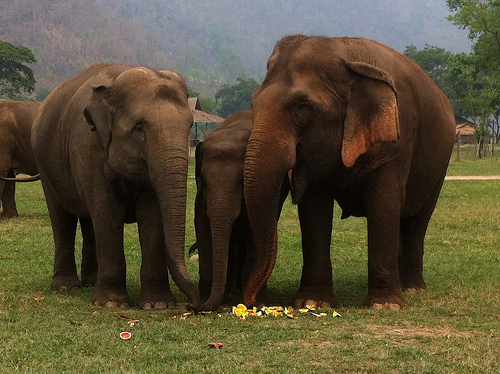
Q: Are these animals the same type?
A: Yes, all the animals are elephants.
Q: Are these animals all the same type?
A: Yes, all the animals are elephants.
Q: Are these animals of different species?
A: No, all the animals are elephants.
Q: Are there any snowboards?
A: No, there are no snowboards.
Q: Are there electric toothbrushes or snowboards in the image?
A: No, there are no snowboards or electric toothbrushes.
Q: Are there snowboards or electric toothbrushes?
A: No, there are no snowboards or electric toothbrushes.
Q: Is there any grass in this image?
A: Yes, there is grass.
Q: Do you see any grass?
A: Yes, there is grass.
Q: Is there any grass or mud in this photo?
A: Yes, there is grass.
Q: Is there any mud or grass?
A: Yes, there is grass.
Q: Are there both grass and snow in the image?
A: No, there is grass but no snow.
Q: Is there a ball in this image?
A: No, there are no balls.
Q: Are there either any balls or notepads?
A: No, there are no balls or notepads.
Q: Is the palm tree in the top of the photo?
A: Yes, the palm tree is in the top of the image.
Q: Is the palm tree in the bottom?
A: No, the palm tree is in the top of the image.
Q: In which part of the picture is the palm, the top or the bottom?
A: The palm is in the top of the image.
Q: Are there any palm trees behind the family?
A: Yes, there is a palm tree behind the family.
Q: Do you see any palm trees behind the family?
A: Yes, there is a palm tree behind the family.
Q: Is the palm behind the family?
A: Yes, the palm is behind the family.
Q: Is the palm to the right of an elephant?
A: Yes, the palm is to the right of an elephant.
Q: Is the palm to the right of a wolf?
A: No, the palm is to the right of an elephant.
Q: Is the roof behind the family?
A: Yes, the roof is behind the family.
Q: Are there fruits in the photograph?
A: Yes, there is a fruit.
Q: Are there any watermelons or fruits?
A: Yes, there is a fruit.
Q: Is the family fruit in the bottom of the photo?
A: Yes, the fruit is in the bottom of the image.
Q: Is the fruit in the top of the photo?
A: No, the fruit is in the bottom of the image.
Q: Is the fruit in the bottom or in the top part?
A: The fruit is in the bottom of the image.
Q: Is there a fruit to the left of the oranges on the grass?
A: Yes, there is a fruit to the left of the oranges.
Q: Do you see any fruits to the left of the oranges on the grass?
A: Yes, there is a fruit to the left of the oranges.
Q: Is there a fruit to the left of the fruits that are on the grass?
A: Yes, there is a fruit to the left of the oranges.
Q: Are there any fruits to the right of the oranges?
A: No, the fruit is to the left of the oranges.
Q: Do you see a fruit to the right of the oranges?
A: No, the fruit is to the left of the oranges.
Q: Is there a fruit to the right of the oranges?
A: No, the fruit is to the left of the oranges.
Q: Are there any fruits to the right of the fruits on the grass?
A: No, the fruit is to the left of the oranges.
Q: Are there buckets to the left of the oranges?
A: No, there is a fruit to the left of the oranges.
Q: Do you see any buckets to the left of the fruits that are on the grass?
A: No, there is a fruit to the left of the oranges.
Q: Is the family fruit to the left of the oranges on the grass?
A: Yes, the fruit is to the left of the oranges.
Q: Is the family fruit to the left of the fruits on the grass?
A: Yes, the fruit is to the left of the oranges.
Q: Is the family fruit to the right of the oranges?
A: No, the fruit is to the left of the oranges.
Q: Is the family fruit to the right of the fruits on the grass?
A: No, the fruit is to the left of the oranges.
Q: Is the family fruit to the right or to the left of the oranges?
A: The fruit is to the left of the oranges.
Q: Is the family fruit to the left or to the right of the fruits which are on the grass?
A: The fruit is to the left of the oranges.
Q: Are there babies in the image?
A: Yes, there is a baby.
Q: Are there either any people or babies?
A: Yes, there is a baby.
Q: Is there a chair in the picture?
A: No, there are no chairs.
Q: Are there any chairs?
A: No, there are no chairs.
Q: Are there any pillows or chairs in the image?
A: No, there are no chairs or pillows.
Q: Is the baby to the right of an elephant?
A: Yes, the baby is to the right of an elephant.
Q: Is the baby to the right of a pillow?
A: No, the baby is to the right of an elephant.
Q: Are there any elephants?
A: Yes, there is an elephant.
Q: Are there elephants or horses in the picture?
A: Yes, there is an elephant.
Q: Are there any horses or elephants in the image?
A: Yes, there is an elephant.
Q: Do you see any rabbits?
A: No, there are no rabbits.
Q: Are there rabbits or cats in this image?
A: No, there are no rabbits or cats.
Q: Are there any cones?
A: No, there are no cones.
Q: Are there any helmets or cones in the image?
A: No, there are no cones or helmets.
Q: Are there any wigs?
A: No, there are no wigs.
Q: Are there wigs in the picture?
A: No, there are no wigs.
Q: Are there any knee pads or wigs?
A: No, there are no wigs or knee pads.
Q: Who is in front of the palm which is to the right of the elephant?
A: The family is in front of the palm.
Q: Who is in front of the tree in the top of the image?
A: The family is in front of the palm.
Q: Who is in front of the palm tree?
A: The family is in front of the palm.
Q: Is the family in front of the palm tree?
A: Yes, the family is in front of the palm tree.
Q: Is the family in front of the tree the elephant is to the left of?
A: Yes, the family is in front of the palm tree.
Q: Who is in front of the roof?
A: The family is in front of the roof.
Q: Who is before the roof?
A: The family is in front of the roof.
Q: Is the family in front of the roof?
A: Yes, the family is in front of the roof.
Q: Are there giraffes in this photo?
A: No, there are no giraffes.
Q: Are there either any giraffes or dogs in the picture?
A: No, there are no giraffes or dogs.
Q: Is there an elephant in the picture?
A: Yes, there is an elephant.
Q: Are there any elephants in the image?
A: Yes, there is an elephant.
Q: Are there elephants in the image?
A: Yes, there is an elephant.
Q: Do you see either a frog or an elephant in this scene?
A: Yes, there is an elephant.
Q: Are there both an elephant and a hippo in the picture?
A: No, there is an elephant but no hippoes.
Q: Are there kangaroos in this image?
A: No, there are no kangaroos.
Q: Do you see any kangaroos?
A: No, there are no kangaroos.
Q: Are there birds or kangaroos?
A: No, there are no kangaroos or birds.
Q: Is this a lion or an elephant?
A: This is an elephant.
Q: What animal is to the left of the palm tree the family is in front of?
A: The animal is an elephant.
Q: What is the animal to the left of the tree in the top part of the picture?
A: The animal is an elephant.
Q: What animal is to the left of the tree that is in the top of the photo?
A: The animal is an elephant.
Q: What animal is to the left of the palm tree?
A: The animal is an elephant.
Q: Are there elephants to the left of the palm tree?
A: Yes, there is an elephant to the left of the palm tree.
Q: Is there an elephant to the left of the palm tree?
A: Yes, there is an elephant to the left of the palm tree.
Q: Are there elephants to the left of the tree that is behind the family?
A: Yes, there is an elephant to the left of the palm tree.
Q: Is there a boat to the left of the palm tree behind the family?
A: No, there is an elephant to the left of the palm tree.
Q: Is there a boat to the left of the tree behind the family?
A: No, there is an elephant to the left of the palm tree.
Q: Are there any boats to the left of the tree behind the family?
A: No, there is an elephant to the left of the palm tree.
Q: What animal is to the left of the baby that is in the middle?
A: The animal is an elephant.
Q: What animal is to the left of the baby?
A: The animal is an elephant.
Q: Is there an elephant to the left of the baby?
A: Yes, there is an elephant to the left of the baby.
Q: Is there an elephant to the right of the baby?
A: No, the elephant is to the left of the baby.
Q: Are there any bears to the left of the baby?
A: No, there is an elephant to the left of the baby.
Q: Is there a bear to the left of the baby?
A: No, there is an elephant to the left of the baby.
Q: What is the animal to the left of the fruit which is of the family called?
A: The animal is an elephant.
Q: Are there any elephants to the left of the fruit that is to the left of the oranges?
A: Yes, there is an elephant to the left of the fruit.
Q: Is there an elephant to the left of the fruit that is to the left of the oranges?
A: Yes, there is an elephant to the left of the fruit.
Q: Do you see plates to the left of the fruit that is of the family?
A: No, there is an elephant to the left of the fruit.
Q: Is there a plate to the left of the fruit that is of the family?
A: No, there is an elephant to the left of the fruit.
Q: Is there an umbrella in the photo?
A: No, there are no umbrellas.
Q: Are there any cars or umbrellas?
A: No, there are no umbrellas or cars.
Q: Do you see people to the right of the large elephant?
A: Yes, there are people to the right of the elephant.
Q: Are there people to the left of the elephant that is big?
A: No, the people are to the right of the elephant.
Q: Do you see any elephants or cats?
A: Yes, there is an elephant.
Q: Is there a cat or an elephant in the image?
A: Yes, there is an elephant.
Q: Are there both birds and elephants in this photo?
A: No, there is an elephant but no birds.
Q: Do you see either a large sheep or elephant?
A: Yes, there is a large elephant.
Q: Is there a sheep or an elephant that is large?
A: Yes, the elephant is large.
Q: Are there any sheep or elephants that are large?
A: Yes, the elephant is large.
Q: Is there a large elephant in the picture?
A: Yes, there is a large elephant.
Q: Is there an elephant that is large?
A: Yes, there is an elephant that is large.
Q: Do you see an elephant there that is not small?
A: Yes, there is a large elephant.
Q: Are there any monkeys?
A: No, there are no monkeys.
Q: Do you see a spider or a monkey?
A: No, there are no monkeys or spiders.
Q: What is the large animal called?
A: The animal is an elephant.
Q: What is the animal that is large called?
A: The animal is an elephant.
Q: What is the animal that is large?
A: The animal is an elephant.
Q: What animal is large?
A: The animal is an elephant.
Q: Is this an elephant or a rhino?
A: This is an elephant.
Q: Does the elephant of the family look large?
A: Yes, the elephant is large.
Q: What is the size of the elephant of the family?
A: The elephant is large.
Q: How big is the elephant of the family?
A: The elephant is large.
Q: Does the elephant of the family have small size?
A: No, the elephant is large.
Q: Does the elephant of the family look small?
A: No, the elephant is large.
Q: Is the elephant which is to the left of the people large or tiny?
A: The elephant is large.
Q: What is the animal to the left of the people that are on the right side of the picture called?
A: The animal is an elephant.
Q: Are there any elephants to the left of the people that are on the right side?
A: Yes, there is an elephant to the left of the people.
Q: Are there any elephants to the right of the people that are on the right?
A: No, the elephant is to the left of the people.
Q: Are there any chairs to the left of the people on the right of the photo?
A: No, there is an elephant to the left of the people.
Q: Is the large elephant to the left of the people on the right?
A: Yes, the elephant is to the left of the people.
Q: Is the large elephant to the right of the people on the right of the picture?
A: No, the elephant is to the left of the people.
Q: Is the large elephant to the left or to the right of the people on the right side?
A: The elephant is to the left of the people.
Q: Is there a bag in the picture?
A: No, there are no bags.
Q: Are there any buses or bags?
A: No, there are no bags or buses.